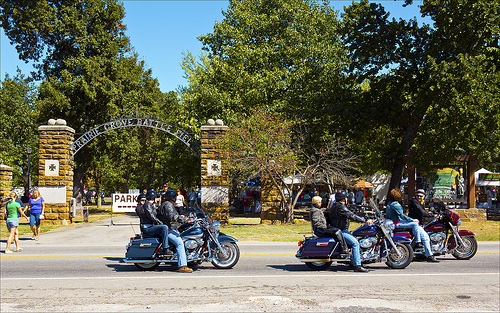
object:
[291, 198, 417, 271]
bike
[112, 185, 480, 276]
group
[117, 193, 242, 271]
bikes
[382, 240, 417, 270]
front wheel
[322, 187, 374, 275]
people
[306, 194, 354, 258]
lady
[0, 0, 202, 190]
trees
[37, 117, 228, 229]
entrance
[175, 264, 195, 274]
shoe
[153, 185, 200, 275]
person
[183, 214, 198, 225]
hand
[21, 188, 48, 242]
girl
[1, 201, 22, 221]
shirt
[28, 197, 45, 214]
shirt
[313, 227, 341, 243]
saddlebag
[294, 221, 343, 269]
back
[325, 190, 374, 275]
man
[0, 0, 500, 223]
park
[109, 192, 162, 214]
parking sign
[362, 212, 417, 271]
front end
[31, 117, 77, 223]
column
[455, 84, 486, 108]
leaves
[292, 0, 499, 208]
tree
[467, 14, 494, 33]
leaves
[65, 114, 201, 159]
sign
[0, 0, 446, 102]
sky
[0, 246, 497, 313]
road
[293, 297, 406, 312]
grease stain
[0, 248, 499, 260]
paint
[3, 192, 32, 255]
each other